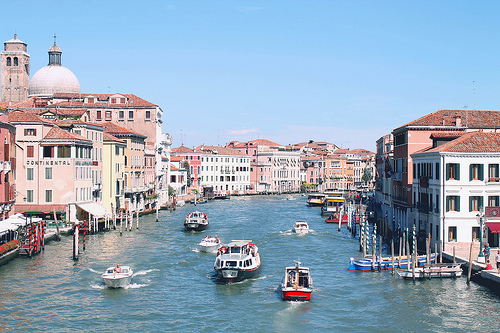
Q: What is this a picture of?
A: A canal.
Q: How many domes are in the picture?
A: One.